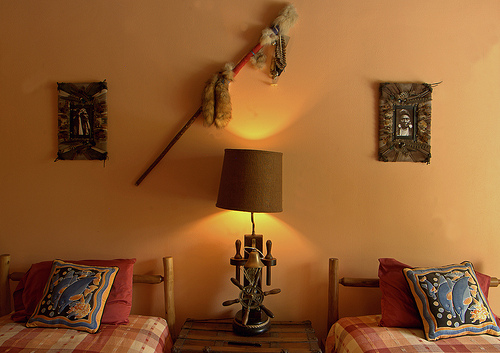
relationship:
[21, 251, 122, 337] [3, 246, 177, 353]
pillow on top of bed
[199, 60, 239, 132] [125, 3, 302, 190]
fur attached to weapon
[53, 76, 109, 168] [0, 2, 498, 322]
photograph mounted on wall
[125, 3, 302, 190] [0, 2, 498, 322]
weapon mounted on wall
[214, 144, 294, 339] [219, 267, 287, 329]
lamp has wheel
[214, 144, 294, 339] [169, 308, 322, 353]
lamp on top of end table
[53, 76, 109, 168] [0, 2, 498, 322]
photograph hanging on wall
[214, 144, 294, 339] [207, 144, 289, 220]
lamp has shade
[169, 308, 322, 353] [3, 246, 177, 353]
end table between bed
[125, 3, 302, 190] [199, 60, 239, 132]
weapon has fur